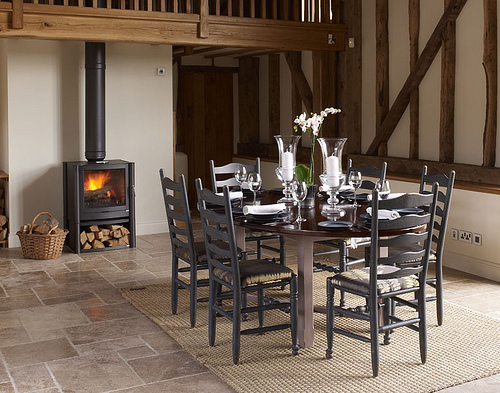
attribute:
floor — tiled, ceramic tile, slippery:
[1, 231, 499, 391]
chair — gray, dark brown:
[209, 156, 287, 295]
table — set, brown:
[199, 184, 431, 351]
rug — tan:
[115, 259, 500, 392]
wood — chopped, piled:
[79, 223, 133, 251]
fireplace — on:
[69, 160, 133, 221]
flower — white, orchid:
[293, 101, 343, 182]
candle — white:
[282, 149, 295, 183]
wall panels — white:
[360, 2, 500, 168]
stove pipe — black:
[84, 40, 110, 164]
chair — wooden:
[194, 177, 300, 364]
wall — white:
[3, 37, 176, 250]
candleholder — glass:
[315, 135, 349, 221]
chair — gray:
[363, 164, 456, 333]